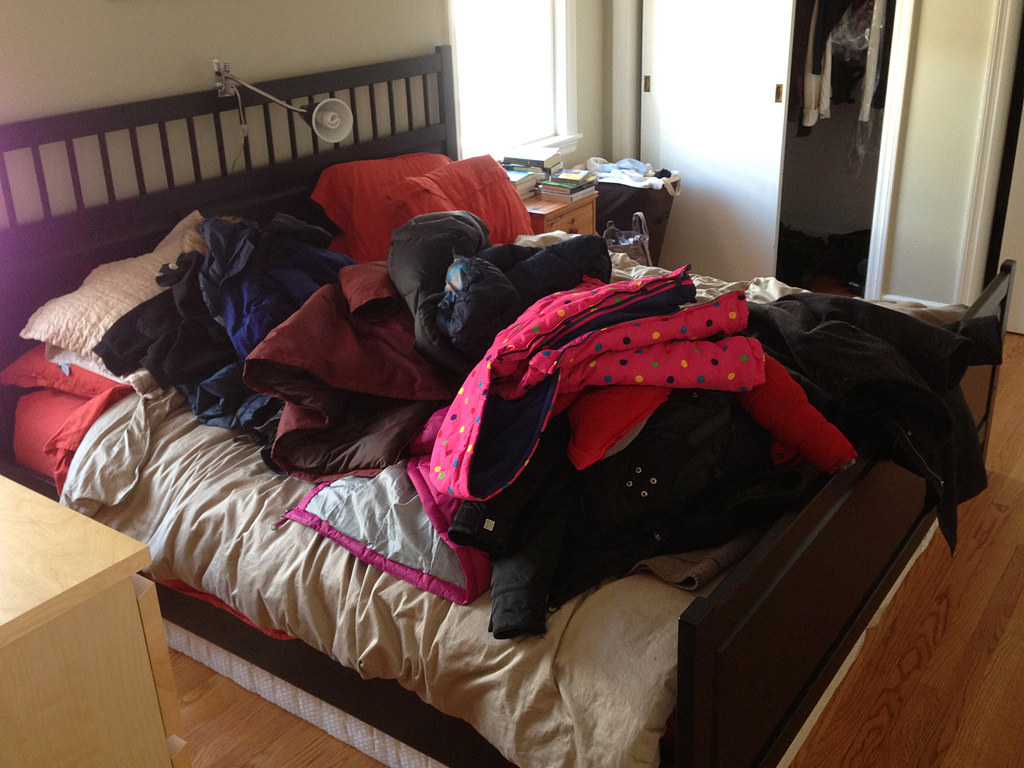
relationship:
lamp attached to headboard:
[201, 41, 360, 161] [4, 35, 455, 299]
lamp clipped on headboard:
[201, 41, 360, 161] [4, 35, 455, 299]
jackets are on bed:
[88, 203, 994, 579] [7, 27, 1014, 754]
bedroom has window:
[0, 6, 1022, 766] [446, 5, 570, 169]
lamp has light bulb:
[201, 41, 360, 161] [320, 105, 344, 133]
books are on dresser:
[538, 161, 599, 211] [520, 167, 602, 235]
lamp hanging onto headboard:
[201, 41, 360, 161] [4, 35, 455, 299]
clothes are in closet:
[792, 8, 913, 135] [607, 6, 991, 317]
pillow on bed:
[349, 142, 546, 268] [7, 27, 1014, 754]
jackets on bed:
[88, 203, 994, 579] [7, 27, 1014, 754]